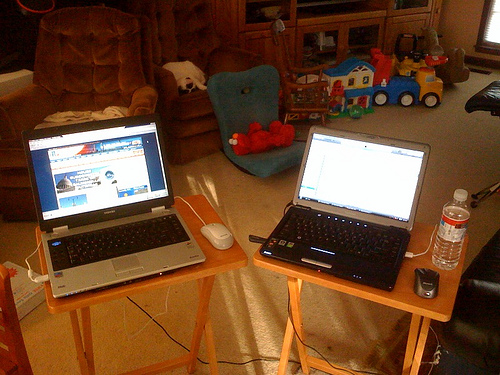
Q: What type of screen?
A: On the computer.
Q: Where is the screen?
A: On the left computer.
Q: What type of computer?
A: Laptop.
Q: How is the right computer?
A: Turn on.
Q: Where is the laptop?
A: On the stand.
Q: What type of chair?
A: Brown chair.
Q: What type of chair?
A: Brown reclining chair.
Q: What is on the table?
A: A laptop.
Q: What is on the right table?
A: A black laptop.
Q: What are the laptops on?
A: Tv tables.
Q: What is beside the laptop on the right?
A: Water.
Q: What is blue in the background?
A: A chair.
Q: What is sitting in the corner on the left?
A: An older chair.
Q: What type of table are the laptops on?
A: A folding table.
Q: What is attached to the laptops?
A: A mouse.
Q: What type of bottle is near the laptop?
A: A water bottle.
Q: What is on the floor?
A: Toys.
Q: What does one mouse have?
A: Cord.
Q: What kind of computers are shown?
A: Laptops.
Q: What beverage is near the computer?
A: Water.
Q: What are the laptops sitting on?
A: Television trays.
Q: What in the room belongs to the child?
A: Toys.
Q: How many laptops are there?
A: Two.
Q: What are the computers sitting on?
A: Trays.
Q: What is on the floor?
A: Toys.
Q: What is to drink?
A: Water.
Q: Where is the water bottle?
A: Tray.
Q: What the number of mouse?
A: Two.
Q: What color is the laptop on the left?
A: Silver.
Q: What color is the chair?
A: Brown.